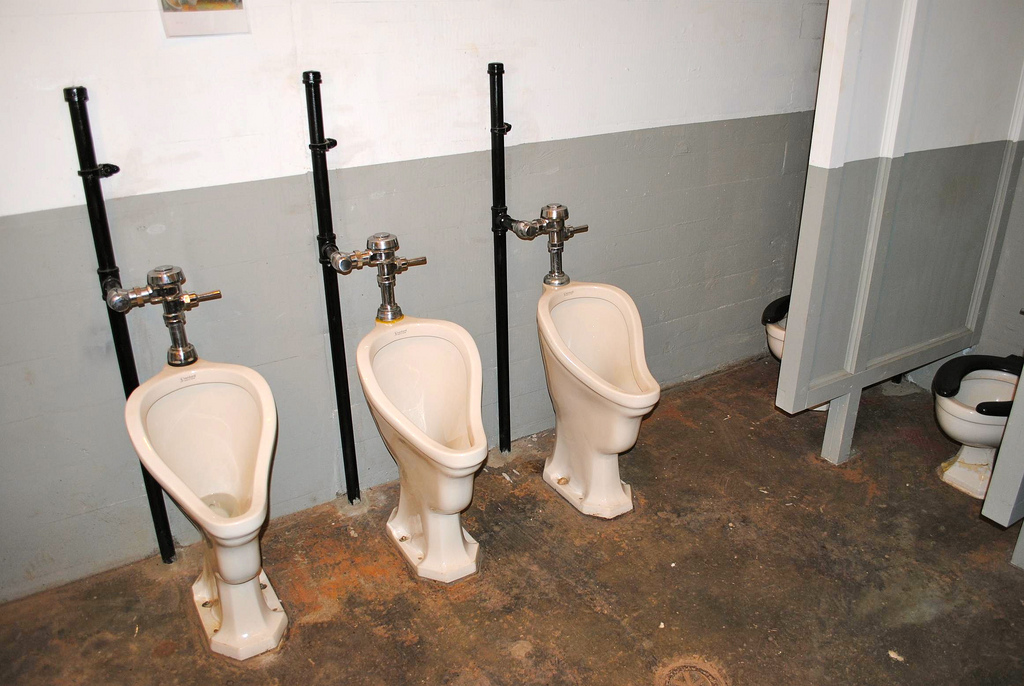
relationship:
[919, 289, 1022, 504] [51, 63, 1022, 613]
toilet in restroom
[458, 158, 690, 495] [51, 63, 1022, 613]
urinal in restroom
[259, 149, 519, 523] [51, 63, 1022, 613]
urinal in restroom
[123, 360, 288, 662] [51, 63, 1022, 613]
urinal in restroom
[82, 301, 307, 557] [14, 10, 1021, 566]
urinal by wall